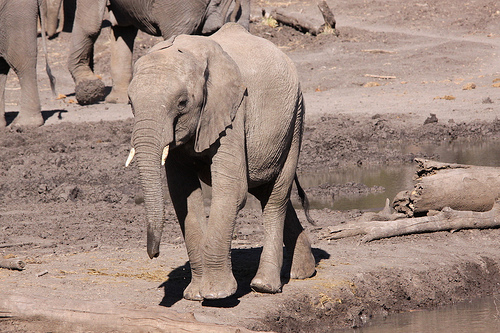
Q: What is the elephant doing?
A: Walking on dirt.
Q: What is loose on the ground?
A: Dirt.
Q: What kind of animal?
A: Elephants.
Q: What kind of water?
A: Drinking hole.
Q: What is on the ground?
A: Log.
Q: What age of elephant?
A: Baby.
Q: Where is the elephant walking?
A: Near water.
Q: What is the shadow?
A: Elephant.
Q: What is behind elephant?
A: Bigger elephants.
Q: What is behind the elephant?
A: Mud.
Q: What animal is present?
A: Elephant.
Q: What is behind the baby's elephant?
A: A log.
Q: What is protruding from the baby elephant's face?
A: Tusks.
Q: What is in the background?
A: A group of elephants.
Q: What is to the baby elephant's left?
A: A watering hole.